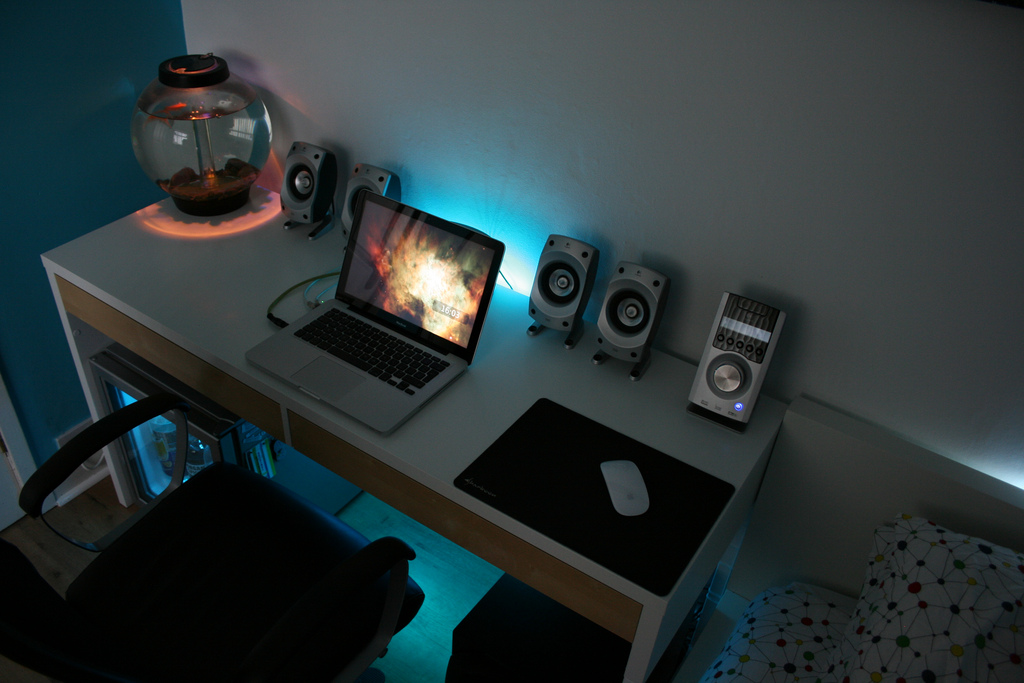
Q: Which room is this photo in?
A: It is at the bedroom.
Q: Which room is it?
A: It is a bedroom.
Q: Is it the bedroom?
A: Yes, it is the bedroom.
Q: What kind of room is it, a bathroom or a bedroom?
A: It is a bedroom.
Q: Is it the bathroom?
A: No, it is the bedroom.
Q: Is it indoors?
A: Yes, it is indoors.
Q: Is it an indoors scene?
A: Yes, it is indoors.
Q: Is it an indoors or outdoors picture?
A: It is indoors.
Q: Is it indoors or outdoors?
A: It is indoors.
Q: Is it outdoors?
A: No, it is indoors.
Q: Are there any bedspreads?
A: No, there are no bedspreads.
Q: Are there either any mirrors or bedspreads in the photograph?
A: No, there are no bedspreads or mirrors.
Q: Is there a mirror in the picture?
A: No, there are no mirrors.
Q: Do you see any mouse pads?
A: Yes, there is a mouse pad.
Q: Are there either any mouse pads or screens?
A: Yes, there is a mouse pad.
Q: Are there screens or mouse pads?
A: Yes, there is a mouse pad.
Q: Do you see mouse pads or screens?
A: Yes, there is a mouse pad.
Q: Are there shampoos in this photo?
A: No, there are no shampoos.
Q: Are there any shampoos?
A: No, there are no shampoos.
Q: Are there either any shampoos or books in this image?
A: No, there are no shampoos or books.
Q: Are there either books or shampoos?
A: No, there are no shampoos or books.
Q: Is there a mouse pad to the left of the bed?
A: Yes, there is a mouse pad to the left of the bed.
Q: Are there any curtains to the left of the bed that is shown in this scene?
A: No, there is a mouse pad to the left of the bed.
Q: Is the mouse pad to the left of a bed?
A: Yes, the mouse pad is to the left of a bed.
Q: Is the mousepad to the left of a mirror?
A: No, the mousepad is to the left of a bed.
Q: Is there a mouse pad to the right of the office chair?
A: Yes, there is a mouse pad to the right of the office chair.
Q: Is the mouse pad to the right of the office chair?
A: Yes, the mouse pad is to the right of the office chair.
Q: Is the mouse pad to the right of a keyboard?
A: No, the mouse pad is to the right of the office chair.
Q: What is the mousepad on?
A: The mousepad is on the desk.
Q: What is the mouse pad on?
A: The mousepad is on the desk.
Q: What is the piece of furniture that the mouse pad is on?
A: The piece of furniture is a desk.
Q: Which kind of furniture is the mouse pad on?
A: The mouse pad is on the desk.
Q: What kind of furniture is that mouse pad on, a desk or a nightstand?
A: The mouse pad is on a desk.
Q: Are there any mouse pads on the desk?
A: Yes, there is a mouse pad on the desk.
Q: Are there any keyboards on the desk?
A: No, there is a mouse pad on the desk.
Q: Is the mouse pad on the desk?
A: Yes, the mouse pad is on the desk.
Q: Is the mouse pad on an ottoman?
A: No, the mouse pad is on the desk.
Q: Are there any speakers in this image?
A: Yes, there is a speaker.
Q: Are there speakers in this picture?
A: Yes, there is a speaker.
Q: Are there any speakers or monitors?
A: Yes, there is a speaker.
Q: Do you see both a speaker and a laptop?
A: Yes, there are both a speaker and a laptop.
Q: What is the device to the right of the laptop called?
A: The device is a speaker.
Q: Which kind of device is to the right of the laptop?
A: The device is a speaker.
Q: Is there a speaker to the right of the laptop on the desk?
A: Yes, there is a speaker to the right of the laptop.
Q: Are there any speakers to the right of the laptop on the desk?
A: Yes, there is a speaker to the right of the laptop.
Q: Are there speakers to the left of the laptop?
A: No, the speaker is to the right of the laptop.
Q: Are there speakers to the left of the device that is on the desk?
A: No, the speaker is to the right of the laptop.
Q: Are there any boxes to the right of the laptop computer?
A: No, there is a speaker to the right of the laptop computer.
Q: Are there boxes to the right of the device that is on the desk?
A: No, there is a speaker to the right of the laptop computer.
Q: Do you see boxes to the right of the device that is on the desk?
A: No, there is a speaker to the right of the laptop computer.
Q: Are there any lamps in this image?
A: No, there are no lamps.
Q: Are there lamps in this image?
A: No, there are no lamps.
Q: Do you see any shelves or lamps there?
A: No, there are no lamps or shelves.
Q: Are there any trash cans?
A: No, there are no trash cans.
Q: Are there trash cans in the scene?
A: No, there are no trash cans.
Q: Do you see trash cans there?
A: No, there are no trash cans.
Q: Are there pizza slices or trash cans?
A: No, there are no trash cans or pizza slices.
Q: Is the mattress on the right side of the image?
A: Yes, the mattress is on the right of the image.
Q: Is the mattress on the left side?
A: No, the mattress is on the right of the image.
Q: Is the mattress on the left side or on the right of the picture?
A: The mattress is on the right of the image.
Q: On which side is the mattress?
A: The mattress is on the right of the image.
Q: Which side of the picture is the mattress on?
A: The mattress is on the right of the image.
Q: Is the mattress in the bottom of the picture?
A: Yes, the mattress is in the bottom of the image.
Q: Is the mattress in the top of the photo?
A: No, the mattress is in the bottom of the image.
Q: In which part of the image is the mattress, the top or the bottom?
A: The mattress is in the bottom of the image.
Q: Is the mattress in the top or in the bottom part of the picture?
A: The mattress is in the bottom of the image.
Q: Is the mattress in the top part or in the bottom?
A: The mattress is in the bottom of the image.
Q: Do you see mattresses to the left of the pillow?
A: Yes, there is a mattress to the left of the pillow.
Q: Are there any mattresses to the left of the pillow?
A: Yes, there is a mattress to the left of the pillow.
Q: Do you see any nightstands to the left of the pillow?
A: No, there is a mattress to the left of the pillow.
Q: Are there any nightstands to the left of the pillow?
A: No, there is a mattress to the left of the pillow.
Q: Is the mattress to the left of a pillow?
A: Yes, the mattress is to the left of a pillow.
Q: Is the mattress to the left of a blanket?
A: No, the mattress is to the left of a pillow.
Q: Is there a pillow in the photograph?
A: Yes, there is a pillow.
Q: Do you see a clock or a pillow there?
A: Yes, there is a pillow.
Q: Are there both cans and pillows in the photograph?
A: No, there is a pillow but no cans.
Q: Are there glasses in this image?
A: No, there are no glasses.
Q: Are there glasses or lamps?
A: No, there are no glasses or lamps.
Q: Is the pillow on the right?
A: Yes, the pillow is on the right of the image.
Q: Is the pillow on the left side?
A: No, the pillow is on the right of the image.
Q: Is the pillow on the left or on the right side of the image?
A: The pillow is on the right of the image.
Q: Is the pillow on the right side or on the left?
A: The pillow is on the right of the image.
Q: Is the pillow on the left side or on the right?
A: The pillow is on the right of the image.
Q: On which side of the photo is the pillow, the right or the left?
A: The pillow is on the right of the image.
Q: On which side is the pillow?
A: The pillow is on the right of the image.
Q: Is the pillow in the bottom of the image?
A: Yes, the pillow is in the bottom of the image.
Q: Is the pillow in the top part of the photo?
A: No, the pillow is in the bottom of the image.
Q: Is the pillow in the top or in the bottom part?
A: The pillow is in the bottom of the image.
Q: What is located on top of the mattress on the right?
A: The pillow is on top of the mattress.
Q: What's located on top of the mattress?
A: The pillow is on top of the mattress.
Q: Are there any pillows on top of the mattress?
A: Yes, there is a pillow on top of the mattress.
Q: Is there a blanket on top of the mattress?
A: No, there is a pillow on top of the mattress.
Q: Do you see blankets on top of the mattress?
A: No, there is a pillow on top of the mattress.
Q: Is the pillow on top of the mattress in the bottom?
A: Yes, the pillow is on top of the mattress.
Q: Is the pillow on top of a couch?
A: No, the pillow is on top of the mattress.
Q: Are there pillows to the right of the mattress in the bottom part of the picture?
A: Yes, there is a pillow to the right of the mattress.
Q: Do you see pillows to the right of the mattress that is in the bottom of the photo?
A: Yes, there is a pillow to the right of the mattress.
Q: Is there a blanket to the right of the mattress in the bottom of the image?
A: No, there is a pillow to the right of the mattress.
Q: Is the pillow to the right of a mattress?
A: Yes, the pillow is to the right of a mattress.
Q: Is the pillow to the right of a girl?
A: No, the pillow is to the right of a mattress.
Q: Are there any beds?
A: Yes, there is a bed.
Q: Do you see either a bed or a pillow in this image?
A: Yes, there is a bed.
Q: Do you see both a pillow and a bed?
A: Yes, there are both a bed and a pillow.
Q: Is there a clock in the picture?
A: No, there are no clocks.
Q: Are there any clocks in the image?
A: No, there are no clocks.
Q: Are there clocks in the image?
A: No, there are no clocks.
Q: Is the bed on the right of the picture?
A: Yes, the bed is on the right of the image.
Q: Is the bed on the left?
A: No, the bed is on the right of the image.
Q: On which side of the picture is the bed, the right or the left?
A: The bed is on the right of the image.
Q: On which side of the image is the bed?
A: The bed is on the right of the image.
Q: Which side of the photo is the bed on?
A: The bed is on the right of the image.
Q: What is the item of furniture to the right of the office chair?
A: The piece of furniture is a bed.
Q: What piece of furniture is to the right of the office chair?
A: The piece of furniture is a bed.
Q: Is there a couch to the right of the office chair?
A: No, there is a bed to the right of the office chair.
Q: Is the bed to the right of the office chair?
A: Yes, the bed is to the right of the office chair.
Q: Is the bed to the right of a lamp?
A: No, the bed is to the right of the office chair.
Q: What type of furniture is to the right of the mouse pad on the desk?
A: The piece of furniture is a bed.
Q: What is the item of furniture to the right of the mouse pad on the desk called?
A: The piece of furniture is a bed.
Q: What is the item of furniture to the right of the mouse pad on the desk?
A: The piece of furniture is a bed.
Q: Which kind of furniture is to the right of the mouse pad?
A: The piece of furniture is a bed.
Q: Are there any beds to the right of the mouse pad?
A: Yes, there is a bed to the right of the mouse pad.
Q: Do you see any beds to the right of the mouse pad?
A: Yes, there is a bed to the right of the mouse pad.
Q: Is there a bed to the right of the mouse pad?
A: Yes, there is a bed to the right of the mouse pad.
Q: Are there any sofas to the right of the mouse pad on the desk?
A: No, there is a bed to the right of the mousepad.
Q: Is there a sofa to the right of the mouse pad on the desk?
A: No, there is a bed to the right of the mousepad.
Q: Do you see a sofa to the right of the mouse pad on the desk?
A: No, there is a bed to the right of the mousepad.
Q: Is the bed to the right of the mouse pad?
A: Yes, the bed is to the right of the mouse pad.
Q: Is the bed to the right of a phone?
A: No, the bed is to the right of the mouse pad.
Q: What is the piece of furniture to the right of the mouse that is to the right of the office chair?
A: The piece of furniture is a bed.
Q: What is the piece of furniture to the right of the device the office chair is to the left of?
A: The piece of furniture is a bed.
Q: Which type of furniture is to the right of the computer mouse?
A: The piece of furniture is a bed.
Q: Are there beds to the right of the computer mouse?
A: Yes, there is a bed to the right of the computer mouse.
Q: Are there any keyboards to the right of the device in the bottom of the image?
A: No, there is a bed to the right of the computer mouse.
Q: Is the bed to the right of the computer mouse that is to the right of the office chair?
A: Yes, the bed is to the right of the mouse.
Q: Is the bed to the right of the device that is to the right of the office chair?
A: Yes, the bed is to the right of the mouse.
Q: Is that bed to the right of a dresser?
A: No, the bed is to the right of the mouse.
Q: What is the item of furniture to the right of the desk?
A: The piece of furniture is a bed.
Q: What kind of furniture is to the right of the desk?
A: The piece of furniture is a bed.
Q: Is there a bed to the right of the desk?
A: Yes, there is a bed to the right of the desk.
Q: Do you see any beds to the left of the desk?
A: No, the bed is to the right of the desk.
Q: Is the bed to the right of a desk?
A: Yes, the bed is to the right of a desk.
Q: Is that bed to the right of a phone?
A: No, the bed is to the right of a desk.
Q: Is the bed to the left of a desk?
A: No, the bed is to the right of a desk.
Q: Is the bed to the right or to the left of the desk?
A: The bed is to the right of the desk.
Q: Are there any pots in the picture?
A: No, there are no pots.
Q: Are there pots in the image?
A: No, there are no pots.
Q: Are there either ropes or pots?
A: No, there are no pots or ropes.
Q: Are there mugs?
A: No, there are no mugs.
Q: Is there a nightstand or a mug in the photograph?
A: No, there are no mugs or nightstands.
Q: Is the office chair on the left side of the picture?
A: Yes, the office chair is on the left of the image.